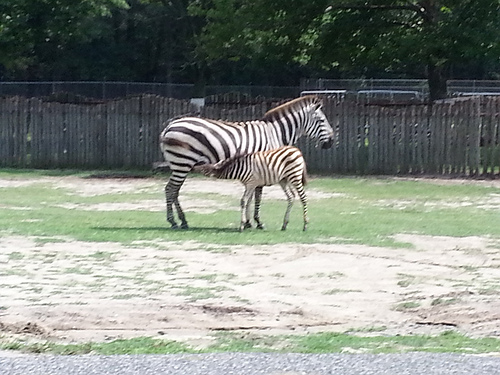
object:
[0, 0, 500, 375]
park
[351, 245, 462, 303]
ground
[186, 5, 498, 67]
green leaves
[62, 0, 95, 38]
green leaves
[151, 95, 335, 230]
zebra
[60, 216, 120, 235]
grass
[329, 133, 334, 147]
nose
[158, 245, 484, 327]
sand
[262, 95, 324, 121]
mane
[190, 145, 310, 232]
baby zebra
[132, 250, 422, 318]
dirt patch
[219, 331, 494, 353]
grass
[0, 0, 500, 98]
trees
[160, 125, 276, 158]
fur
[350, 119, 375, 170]
whole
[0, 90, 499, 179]
fence